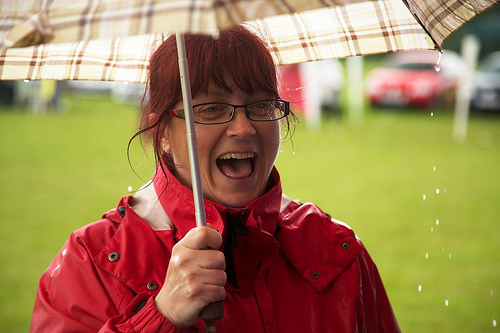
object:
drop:
[426, 109, 436, 115]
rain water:
[431, 64, 444, 75]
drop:
[433, 185, 441, 195]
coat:
[29, 157, 400, 332]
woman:
[28, 26, 402, 332]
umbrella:
[2, 0, 499, 330]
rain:
[420, 193, 430, 204]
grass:
[0, 104, 500, 332]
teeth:
[223, 152, 230, 159]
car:
[363, 48, 464, 111]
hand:
[154, 224, 230, 328]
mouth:
[213, 148, 260, 183]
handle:
[172, 29, 211, 227]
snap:
[105, 252, 120, 264]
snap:
[143, 280, 159, 294]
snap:
[311, 270, 323, 279]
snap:
[341, 241, 351, 251]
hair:
[121, 23, 298, 205]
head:
[140, 28, 284, 209]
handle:
[195, 297, 229, 332]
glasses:
[164, 97, 293, 126]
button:
[105, 251, 123, 264]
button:
[145, 281, 160, 291]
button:
[309, 267, 325, 280]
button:
[338, 240, 355, 250]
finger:
[176, 223, 226, 250]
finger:
[194, 248, 230, 269]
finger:
[197, 266, 229, 286]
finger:
[200, 283, 228, 303]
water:
[415, 281, 425, 291]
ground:
[0, 97, 500, 332]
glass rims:
[244, 96, 289, 108]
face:
[164, 66, 280, 208]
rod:
[171, 30, 207, 227]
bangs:
[165, 29, 280, 101]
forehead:
[175, 35, 280, 95]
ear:
[145, 110, 170, 154]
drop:
[431, 63, 444, 73]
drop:
[415, 283, 423, 295]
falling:
[431, 164, 442, 174]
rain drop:
[447, 252, 455, 262]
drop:
[490, 317, 500, 328]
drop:
[487, 287, 497, 301]